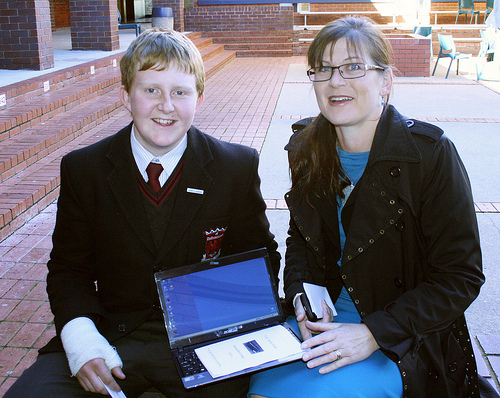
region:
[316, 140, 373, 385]
the dress is blue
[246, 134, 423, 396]
the dress is blue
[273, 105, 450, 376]
the jacket is black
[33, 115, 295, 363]
the jacket is black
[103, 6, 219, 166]
The boy is smiling.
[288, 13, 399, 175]
The woman is smiling.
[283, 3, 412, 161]
The woman is wearing glasses.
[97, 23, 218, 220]
The boy is wearing a tie.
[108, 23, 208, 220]
The boy's tie is red.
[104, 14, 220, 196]
The boy has short hair.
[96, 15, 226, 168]
The boy's hair is blonde.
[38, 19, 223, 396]
Boy's right hand is in a cast.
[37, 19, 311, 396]
The boy is holding a laptop.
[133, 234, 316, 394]
The laptop is open.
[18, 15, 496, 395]
Woman and young boy sitting on bench.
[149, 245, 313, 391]
Young boy holding ipad in hand.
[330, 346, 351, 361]
Woman wearing wedding ring on finger of left hand.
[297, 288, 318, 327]
Woman holding cell phone in hand.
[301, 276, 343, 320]
Woman holding white envelope in hand.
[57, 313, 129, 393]
Boy's right hand is bandaged.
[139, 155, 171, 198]
Young boy wearing maroon tie around neck.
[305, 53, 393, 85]
Woman wearing eyeglasses over eyes.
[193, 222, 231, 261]
Maroon insignia on young boy's coat pocket.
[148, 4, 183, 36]
Trash can sitting at top of steps behind boy and woman.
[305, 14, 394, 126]
A woman wearing prescription eyeglasses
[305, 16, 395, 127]
Lady with hair pulled back and side swept bangs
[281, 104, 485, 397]
A black jacket with metal eyelets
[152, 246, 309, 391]
A black laptop computer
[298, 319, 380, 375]
A woman's hand with wedding band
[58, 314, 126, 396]
A hand partially wrapped in white gauze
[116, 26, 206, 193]
A boy wearing a dress shirt and tie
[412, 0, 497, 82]
Several green resin patio chairs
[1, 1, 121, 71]
A pair of brick columns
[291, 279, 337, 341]
A hand holding a cell phone and piece of paper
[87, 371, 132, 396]
Splint on injured finger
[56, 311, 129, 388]
Cast on injured hand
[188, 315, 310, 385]
Pamphlet on lap top key board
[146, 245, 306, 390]
Lap top computer opened up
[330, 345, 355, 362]
Ring on ring finger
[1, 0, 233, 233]
Brick steps going up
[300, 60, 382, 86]
Women's dark rimmed eyeglasses with gold trim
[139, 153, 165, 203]
Burgundy tie tucked into vest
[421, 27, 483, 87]
Turquoise blue chair on cement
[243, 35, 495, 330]
Gray cement patio area with brick divisions